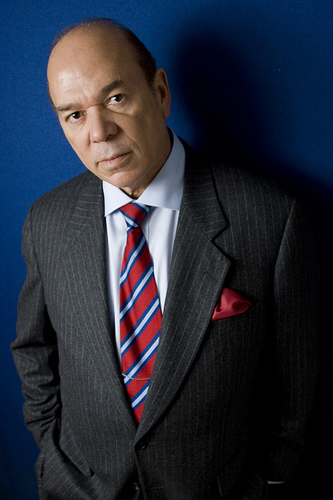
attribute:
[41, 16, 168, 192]
man — one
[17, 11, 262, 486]
man — wearing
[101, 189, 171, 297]
shirt — white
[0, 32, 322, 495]
person — posing 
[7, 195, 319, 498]
suit — black 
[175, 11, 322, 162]
background — blue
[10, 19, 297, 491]
person — single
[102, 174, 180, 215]
collar — white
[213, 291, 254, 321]
object — red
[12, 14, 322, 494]
man —  looking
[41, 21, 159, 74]
head — bald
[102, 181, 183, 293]
shirt — white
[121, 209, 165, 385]
tie — blue, white, red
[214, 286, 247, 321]
kerchief — red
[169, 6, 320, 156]
wall — blue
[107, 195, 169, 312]
shirt — blue, light, collared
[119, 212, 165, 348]
tie —  stripe, white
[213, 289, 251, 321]
handkerchief — red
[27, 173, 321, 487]
jacket —  breast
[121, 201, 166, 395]
tie — blue , white, red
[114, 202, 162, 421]
tie — red, white, blue, striped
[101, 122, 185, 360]
shirt — blue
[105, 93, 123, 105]
eye — black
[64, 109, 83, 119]
eye — black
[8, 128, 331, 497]
jacket — black, lined